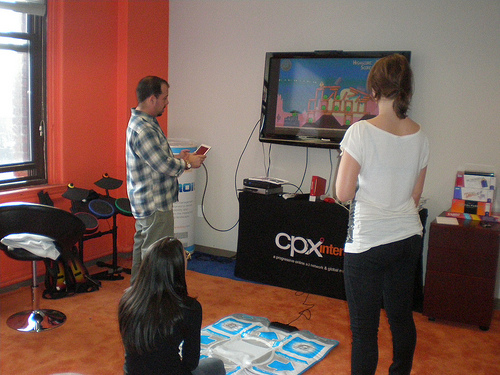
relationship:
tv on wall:
[263, 53, 409, 150] [168, 2, 497, 258]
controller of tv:
[189, 147, 213, 158] [263, 53, 409, 150]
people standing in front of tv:
[127, 56, 421, 351] [263, 53, 409, 150]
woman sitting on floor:
[121, 238, 225, 375] [3, 255, 500, 374]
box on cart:
[455, 171, 490, 218] [427, 216, 496, 326]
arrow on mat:
[267, 361, 301, 373] [195, 315, 323, 373]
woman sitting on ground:
[121, 238, 225, 375] [3, 255, 500, 374]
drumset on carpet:
[64, 179, 144, 279] [3, 255, 500, 374]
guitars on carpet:
[35, 196, 96, 293] [3, 255, 500, 374]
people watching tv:
[331, 48, 434, 375] [263, 53, 409, 150]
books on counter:
[441, 210, 492, 220] [432, 207, 500, 231]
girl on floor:
[121, 238, 225, 375] [3, 255, 500, 374]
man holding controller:
[130, 76, 182, 242] [189, 147, 213, 158]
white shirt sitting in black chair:
[5, 233, 58, 258] [1, 204, 85, 331]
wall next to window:
[2, 2, 168, 286] [1, 2, 43, 185]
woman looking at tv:
[121, 238, 225, 375] [263, 53, 409, 150]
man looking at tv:
[130, 76, 182, 242] [263, 53, 409, 150]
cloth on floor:
[195, 315, 323, 373] [3, 255, 500, 374]